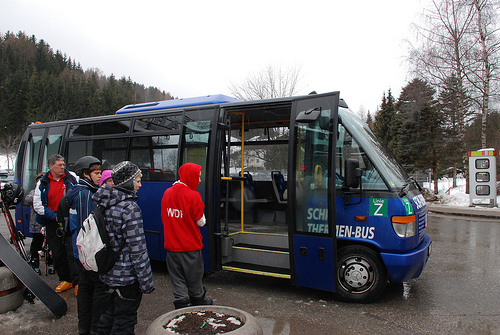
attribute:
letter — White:
[353, 226, 362, 242]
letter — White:
[361, 227, 368, 238]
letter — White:
[368, 228, 375, 240]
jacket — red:
[160, 162, 203, 251]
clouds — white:
[283, 13, 388, 63]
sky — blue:
[12, 2, 484, 92]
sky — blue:
[93, 0, 332, 74]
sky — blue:
[61, 0, 306, 95]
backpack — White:
[73, 195, 128, 280]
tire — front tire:
[333, 248, 383, 301]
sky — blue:
[69, 2, 405, 55]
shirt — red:
[35, 170, 80, 217]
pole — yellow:
[239, 117, 247, 232]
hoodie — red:
[158, 157, 207, 252]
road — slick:
[0, 185, 497, 334]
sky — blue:
[286, 12, 393, 54]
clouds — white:
[168, 4, 360, 109]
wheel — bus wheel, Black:
[331, 245, 385, 301]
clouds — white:
[5, 0, 97, 68]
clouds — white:
[48, 25, 97, 58]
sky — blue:
[3, 0, 496, 127]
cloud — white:
[90, 39, 172, 87]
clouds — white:
[316, 41, 396, 102]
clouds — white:
[239, 17, 290, 66]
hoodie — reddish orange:
[159, 159, 204, 250]